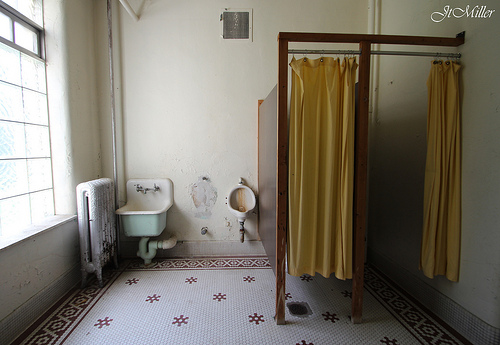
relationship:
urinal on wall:
[226, 179, 259, 242] [96, 3, 371, 260]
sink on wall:
[115, 179, 180, 264] [96, 3, 371, 260]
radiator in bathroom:
[76, 176, 122, 286] [1, 0, 500, 344]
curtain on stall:
[289, 53, 351, 284] [253, 31, 474, 329]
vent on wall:
[217, 5, 258, 46] [96, 3, 371, 260]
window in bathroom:
[1, 1, 51, 63] [1, 0, 500, 344]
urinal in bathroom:
[226, 179, 259, 242] [1, 0, 500, 344]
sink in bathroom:
[115, 179, 180, 264] [1, 0, 500, 344]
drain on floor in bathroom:
[286, 297, 317, 320] [1, 0, 500, 344]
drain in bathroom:
[286, 297, 317, 320] [1, 0, 500, 344]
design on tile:
[167, 308, 194, 328] [8, 256, 480, 344]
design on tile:
[145, 283, 165, 304] [8, 256, 480, 344]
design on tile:
[211, 282, 221, 307] [8, 256, 480, 344]